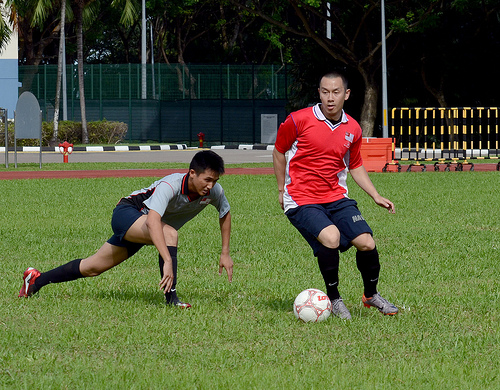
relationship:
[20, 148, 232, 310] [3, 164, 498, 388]
player falling towards ground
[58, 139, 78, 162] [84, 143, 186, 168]
hydrant by street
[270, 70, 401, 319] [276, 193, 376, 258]
player wearing blue shorts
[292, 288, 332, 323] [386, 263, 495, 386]
soccer ball on ground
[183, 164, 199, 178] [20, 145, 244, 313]
ear of a man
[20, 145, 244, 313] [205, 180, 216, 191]
man has nose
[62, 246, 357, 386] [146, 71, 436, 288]
grass beneath players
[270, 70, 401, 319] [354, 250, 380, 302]
player wearing socks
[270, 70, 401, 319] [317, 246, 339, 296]
player wearing socks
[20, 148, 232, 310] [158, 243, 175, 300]
player wearing socks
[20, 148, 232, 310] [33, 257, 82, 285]
player wearing socks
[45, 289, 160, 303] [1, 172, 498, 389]
shadow cast on grass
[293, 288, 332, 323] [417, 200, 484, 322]
ball on field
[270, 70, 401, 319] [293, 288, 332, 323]
player controlling ball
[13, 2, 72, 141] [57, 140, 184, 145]
tree on grass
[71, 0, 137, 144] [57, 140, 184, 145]
tree on grass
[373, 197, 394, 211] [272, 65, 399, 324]
left hand of man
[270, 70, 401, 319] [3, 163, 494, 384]
player on field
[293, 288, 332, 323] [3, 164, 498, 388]
ball on ground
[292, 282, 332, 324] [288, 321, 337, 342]
soccer ball on groud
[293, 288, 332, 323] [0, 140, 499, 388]
ball on ground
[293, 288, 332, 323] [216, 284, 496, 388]
ball on ground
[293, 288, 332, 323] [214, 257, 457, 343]
ball on ground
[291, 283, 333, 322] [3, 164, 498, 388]
ball on ground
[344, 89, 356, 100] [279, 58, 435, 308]
ear of man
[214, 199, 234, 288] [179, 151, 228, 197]
arm of man